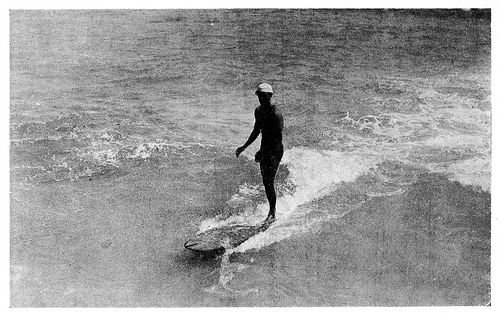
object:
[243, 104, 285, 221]
swim gear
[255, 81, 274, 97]
cap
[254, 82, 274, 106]
head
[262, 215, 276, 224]
feet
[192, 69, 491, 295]
wave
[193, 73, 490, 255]
foam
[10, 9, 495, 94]
ripples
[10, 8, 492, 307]
ocean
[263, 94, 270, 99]
skin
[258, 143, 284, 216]
shorts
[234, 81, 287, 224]
man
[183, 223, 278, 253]
surfboard